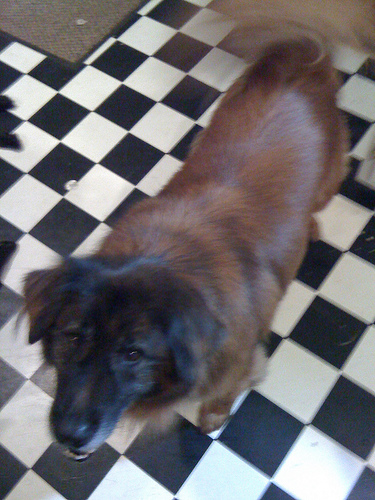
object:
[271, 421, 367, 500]
tile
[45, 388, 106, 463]
snout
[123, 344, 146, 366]
eye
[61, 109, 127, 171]
pattern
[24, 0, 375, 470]
dog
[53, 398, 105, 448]
nose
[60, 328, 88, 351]
brown eye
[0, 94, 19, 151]
paws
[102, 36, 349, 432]
dog's body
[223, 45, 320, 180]
back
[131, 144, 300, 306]
fur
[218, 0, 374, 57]
tail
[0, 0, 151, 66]
rug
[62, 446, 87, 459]
teeth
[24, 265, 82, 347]
ears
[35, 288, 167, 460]
face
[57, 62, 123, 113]
tile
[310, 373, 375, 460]
black/white floor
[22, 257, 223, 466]
hair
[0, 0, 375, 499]
floor